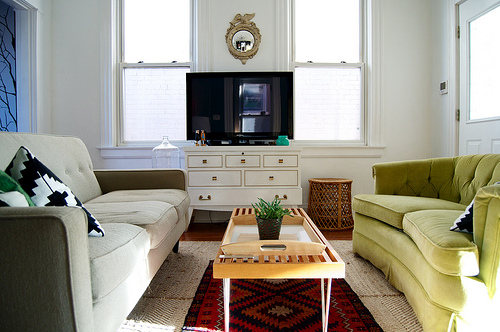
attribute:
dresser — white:
[187, 147, 304, 209]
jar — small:
[272, 133, 291, 144]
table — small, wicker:
[205, 187, 360, 324]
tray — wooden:
[220, 212, 327, 256]